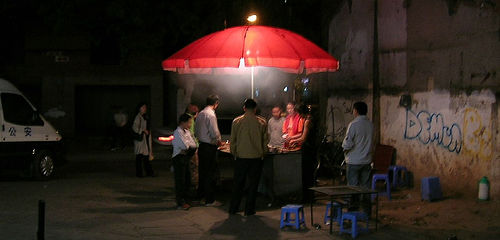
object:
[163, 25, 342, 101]
umbrella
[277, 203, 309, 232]
stool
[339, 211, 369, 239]
stool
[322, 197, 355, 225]
stool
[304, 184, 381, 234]
black table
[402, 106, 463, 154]
graffiti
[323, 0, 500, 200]
wall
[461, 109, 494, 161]
graffiti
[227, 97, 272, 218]
man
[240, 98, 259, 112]
head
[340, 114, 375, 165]
jacket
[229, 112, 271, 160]
jacket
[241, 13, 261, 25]
light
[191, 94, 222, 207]
person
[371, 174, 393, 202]
chair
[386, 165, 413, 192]
chair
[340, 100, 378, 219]
man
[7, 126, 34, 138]
asian charaacter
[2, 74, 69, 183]
van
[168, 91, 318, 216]
people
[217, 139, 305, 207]
cart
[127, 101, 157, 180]
lady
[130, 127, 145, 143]
black purse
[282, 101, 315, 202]
two people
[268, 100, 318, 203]
three people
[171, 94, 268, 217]
four people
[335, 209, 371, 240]
small stools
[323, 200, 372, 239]
stools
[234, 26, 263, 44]
light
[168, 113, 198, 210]
man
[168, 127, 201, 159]
shirt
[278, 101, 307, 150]
person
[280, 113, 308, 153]
orange shirt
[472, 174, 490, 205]
jag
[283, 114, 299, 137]
scarf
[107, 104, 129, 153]
lady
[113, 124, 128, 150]
pants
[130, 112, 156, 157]
coat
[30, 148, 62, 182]
front tire